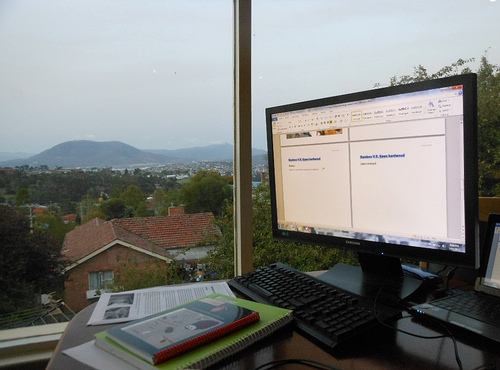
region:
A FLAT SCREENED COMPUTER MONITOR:
[262, 68, 484, 275]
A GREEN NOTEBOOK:
[91, 289, 300, 369]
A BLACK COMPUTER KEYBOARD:
[224, 257, 407, 362]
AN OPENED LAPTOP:
[408, 211, 497, 356]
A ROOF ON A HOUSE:
[56, 214, 174, 280]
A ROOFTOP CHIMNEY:
[166, 202, 188, 218]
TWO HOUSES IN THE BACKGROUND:
[58, 201, 228, 318]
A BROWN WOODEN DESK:
[39, 263, 491, 366]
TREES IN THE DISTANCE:
[98, 166, 229, 213]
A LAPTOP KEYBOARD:
[412, 284, 499, 355]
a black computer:
[195, 60, 494, 334]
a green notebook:
[99, 282, 297, 369]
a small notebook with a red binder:
[99, 284, 276, 366]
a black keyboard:
[221, 243, 419, 368]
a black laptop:
[377, 180, 497, 354]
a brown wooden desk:
[64, 273, 468, 367]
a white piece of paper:
[81, 272, 259, 336]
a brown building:
[46, 190, 257, 290]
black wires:
[216, 303, 493, 368]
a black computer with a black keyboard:
[208, 88, 463, 357]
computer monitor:
[264, 88, 473, 275]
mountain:
[52, 145, 133, 179]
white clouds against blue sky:
[6, 15, 64, 55]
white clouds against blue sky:
[18, 46, 92, 107]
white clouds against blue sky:
[27, 93, 66, 135]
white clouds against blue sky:
[69, 72, 127, 103]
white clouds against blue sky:
[130, 77, 182, 127]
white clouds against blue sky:
[82, 30, 168, 65]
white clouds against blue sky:
[264, 19, 295, 61]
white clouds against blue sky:
[326, 21, 391, 68]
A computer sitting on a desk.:
[29, 15, 481, 368]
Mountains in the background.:
[13, 69, 267, 184]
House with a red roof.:
[46, 199, 239, 300]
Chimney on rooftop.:
[159, 194, 196, 226]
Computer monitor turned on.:
[257, 71, 484, 273]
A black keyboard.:
[224, 249, 399, 352]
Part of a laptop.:
[407, 202, 497, 353]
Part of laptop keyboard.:
[408, 275, 498, 347]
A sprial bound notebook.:
[96, 297, 296, 367]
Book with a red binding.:
[92, 301, 264, 361]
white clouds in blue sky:
[8, 9, 74, 77]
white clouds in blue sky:
[10, 43, 83, 103]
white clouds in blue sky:
[84, 20, 157, 88]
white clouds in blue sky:
[164, 3, 206, 72]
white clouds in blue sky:
[148, 82, 198, 126]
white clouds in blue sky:
[264, 1, 324, 51]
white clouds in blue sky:
[286, 33, 349, 77]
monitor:
[275, 90, 473, 272]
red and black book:
[124, 287, 258, 353]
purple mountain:
[65, 133, 128, 164]